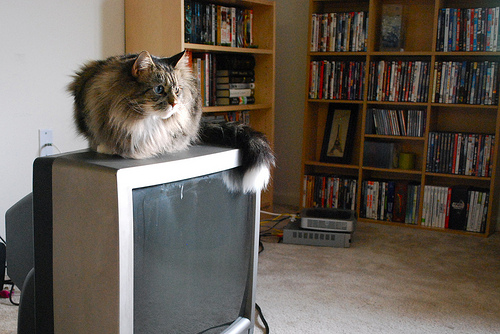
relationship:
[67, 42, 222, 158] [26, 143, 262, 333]
cat in top of television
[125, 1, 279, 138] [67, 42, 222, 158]
shelf behind cat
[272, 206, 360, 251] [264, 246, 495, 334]
electronics on carpet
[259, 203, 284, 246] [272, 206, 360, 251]
wires attached to equipment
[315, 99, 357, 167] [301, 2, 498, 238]
picture on shelf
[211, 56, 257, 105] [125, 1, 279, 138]
books stacked on shelf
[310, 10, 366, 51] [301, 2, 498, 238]
dvds sitting on shelve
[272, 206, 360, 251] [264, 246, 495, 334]
appliances sitting on floor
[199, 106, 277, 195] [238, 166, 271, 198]
tail with white tip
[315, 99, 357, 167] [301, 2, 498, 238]
picture sitting on shelf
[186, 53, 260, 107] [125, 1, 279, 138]
books stacked on shelf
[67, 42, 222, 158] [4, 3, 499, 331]
cat in a room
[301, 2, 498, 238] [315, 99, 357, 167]
shelve fill with artwork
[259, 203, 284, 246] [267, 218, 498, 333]
cords are on floor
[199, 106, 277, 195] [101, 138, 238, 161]
tail curved over top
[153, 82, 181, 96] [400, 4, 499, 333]
eyes looking ahead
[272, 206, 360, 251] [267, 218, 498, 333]
dvd player sitting on floor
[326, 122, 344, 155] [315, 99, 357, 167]
eiffel tower depicting in artwork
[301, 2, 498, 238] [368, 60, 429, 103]
shelf holding video games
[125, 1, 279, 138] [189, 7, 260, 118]
shelf holding movies and books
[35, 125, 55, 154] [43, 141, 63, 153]
outlet for cable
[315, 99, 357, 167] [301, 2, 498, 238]
artwork sitting on shelf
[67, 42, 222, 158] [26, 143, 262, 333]
cat on top of television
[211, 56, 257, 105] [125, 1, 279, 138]
books are on shelf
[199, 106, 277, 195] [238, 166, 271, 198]
tail has white tip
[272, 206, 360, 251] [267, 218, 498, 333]
boxes are on floor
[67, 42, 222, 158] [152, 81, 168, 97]
cat has blue eye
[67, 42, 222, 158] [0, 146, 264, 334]
cat sitting on television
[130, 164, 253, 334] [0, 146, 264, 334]
screen on television